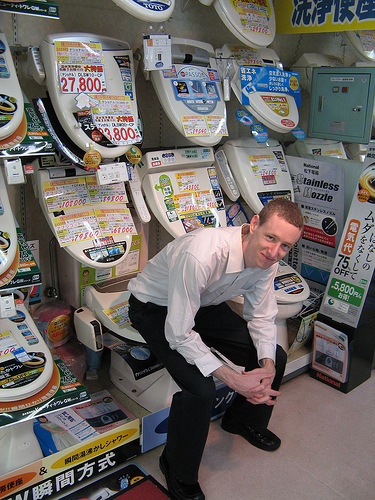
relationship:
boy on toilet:
[126, 198, 304, 500] [74, 271, 182, 381]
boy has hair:
[126, 198, 304, 500] [248, 194, 305, 237]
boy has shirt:
[99, 180, 321, 306] [127, 223, 279, 378]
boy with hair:
[126, 198, 304, 500] [257, 192, 310, 245]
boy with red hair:
[126, 198, 304, 500] [279, 204, 299, 223]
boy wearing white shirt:
[126, 198, 304, 500] [129, 220, 279, 369]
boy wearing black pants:
[126, 198, 304, 500] [138, 318, 282, 474]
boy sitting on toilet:
[126, 198, 304, 500] [119, 317, 182, 380]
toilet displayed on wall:
[0, 29, 27, 142] [0, 0, 374, 316]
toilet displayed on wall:
[24, 30, 144, 172] [0, 0, 374, 316]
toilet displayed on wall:
[140, 35, 230, 148] [0, 0, 374, 316]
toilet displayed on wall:
[212, 40, 302, 134] [0, 0, 374, 316]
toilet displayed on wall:
[25, 152, 135, 269] [0, 0, 374, 316]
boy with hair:
[126, 198, 304, 500] [243, 189, 311, 235]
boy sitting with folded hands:
[126, 198, 304, 500] [218, 342, 333, 417]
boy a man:
[126, 198, 304, 500] [117, 193, 297, 342]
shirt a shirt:
[127, 223, 279, 378] [128, 221, 278, 376]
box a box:
[0, 388, 140, 499] [52, 394, 147, 476]